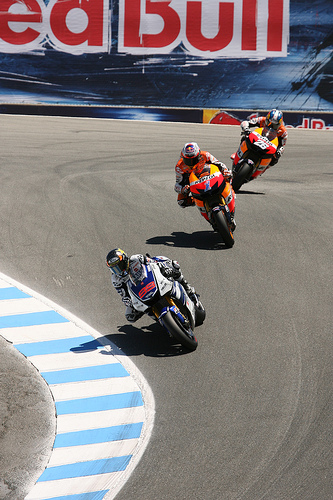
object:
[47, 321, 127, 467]
strips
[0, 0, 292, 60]
slogan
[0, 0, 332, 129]
sign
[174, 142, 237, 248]
person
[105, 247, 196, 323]
person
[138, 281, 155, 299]
99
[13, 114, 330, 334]
road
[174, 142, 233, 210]
man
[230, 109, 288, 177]
person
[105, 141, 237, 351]
motorcyclke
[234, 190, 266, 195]
shadow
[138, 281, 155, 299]
number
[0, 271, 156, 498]
strips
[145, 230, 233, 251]
shadow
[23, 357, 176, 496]
strips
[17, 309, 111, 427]
stripes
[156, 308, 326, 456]
track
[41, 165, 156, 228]
trask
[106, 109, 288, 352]
people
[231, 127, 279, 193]
motorbikes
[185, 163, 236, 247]
motorbikes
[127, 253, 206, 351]
motorbikes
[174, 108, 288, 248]
bikes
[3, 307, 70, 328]
strips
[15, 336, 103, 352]
strips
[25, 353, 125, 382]
strips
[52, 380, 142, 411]
strips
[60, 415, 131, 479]
strips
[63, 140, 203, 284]
marks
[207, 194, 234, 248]
tire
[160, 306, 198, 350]
tire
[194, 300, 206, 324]
tire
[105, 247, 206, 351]
person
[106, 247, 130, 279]
wristwatch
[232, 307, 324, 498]
tracks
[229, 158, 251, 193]
tire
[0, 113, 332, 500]
ground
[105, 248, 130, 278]
helmet